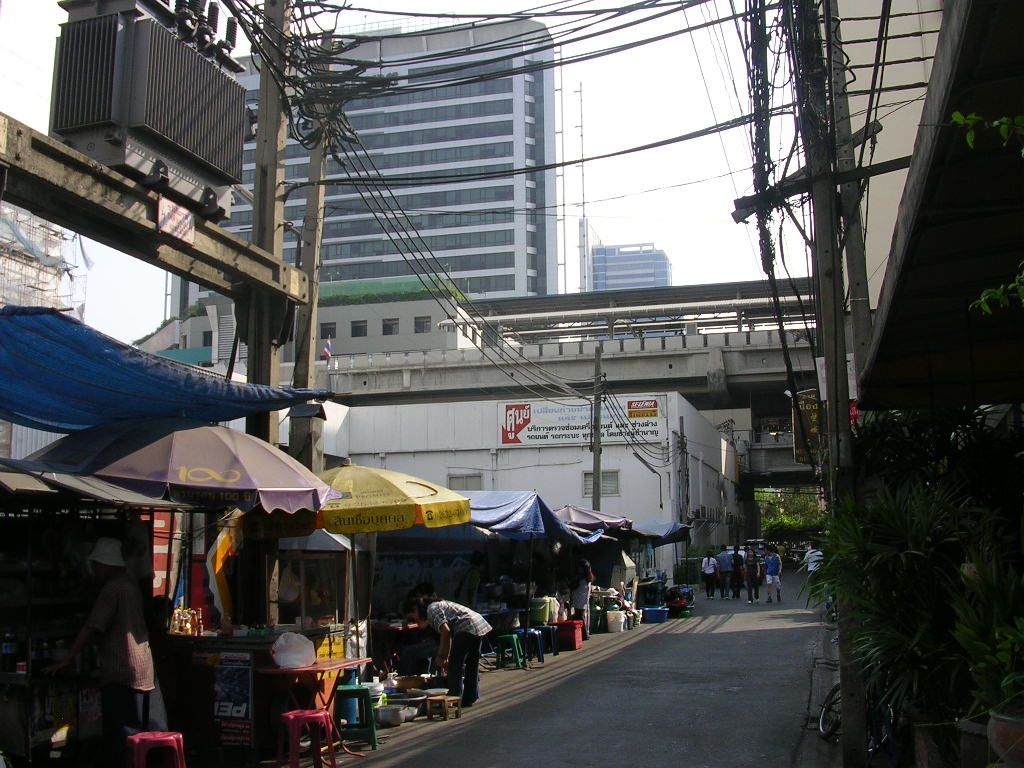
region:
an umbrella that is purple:
[141, 428, 306, 517]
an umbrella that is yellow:
[308, 450, 448, 536]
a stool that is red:
[285, 691, 339, 750]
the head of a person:
[378, 590, 435, 632]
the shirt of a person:
[416, 597, 483, 649]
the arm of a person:
[414, 624, 465, 669]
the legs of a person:
[443, 616, 501, 703]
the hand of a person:
[430, 650, 447, 669]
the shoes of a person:
[462, 700, 488, 708]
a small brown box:
[405, 690, 457, 726]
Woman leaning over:
[415, 594, 496, 715]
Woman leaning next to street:
[416, 589, 497, 713]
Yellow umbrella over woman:
[304, 447, 498, 714]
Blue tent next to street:
[454, 482, 598, 657]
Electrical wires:
[239, 1, 875, 138]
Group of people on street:
[694, 532, 794, 618]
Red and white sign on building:
[492, 389, 671, 450]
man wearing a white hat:
[45, 532, 167, 738]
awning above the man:
[12, 459, 193, 520]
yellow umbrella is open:
[286, 459, 474, 533]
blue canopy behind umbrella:
[378, 482, 600, 550]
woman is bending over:
[401, 596, 493, 704]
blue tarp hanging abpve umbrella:
[1, 301, 334, 441]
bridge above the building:
[222, 321, 824, 401]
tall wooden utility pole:
[287, 32, 335, 463]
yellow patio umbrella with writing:
[288, 455, 479, 544]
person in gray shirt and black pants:
[414, 588, 494, 707]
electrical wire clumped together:
[233, 5, 393, 158]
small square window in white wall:
[408, 304, 437, 340]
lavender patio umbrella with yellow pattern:
[16, 411, 336, 517]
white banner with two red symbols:
[489, 394, 682, 455]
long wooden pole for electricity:
[279, 82, 338, 472]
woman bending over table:
[403, 583, 506, 704]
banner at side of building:
[476, 365, 707, 461]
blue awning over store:
[25, 299, 345, 437]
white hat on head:
[52, 531, 167, 582]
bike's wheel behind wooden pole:
[783, 651, 927, 763]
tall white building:
[366, 14, 617, 284]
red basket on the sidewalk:
[524, 607, 622, 668]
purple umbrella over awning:
[75, 398, 364, 558]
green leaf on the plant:
[920, 568, 984, 651]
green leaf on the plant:
[917, 503, 966, 571]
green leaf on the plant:
[943, 620, 1004, 707]